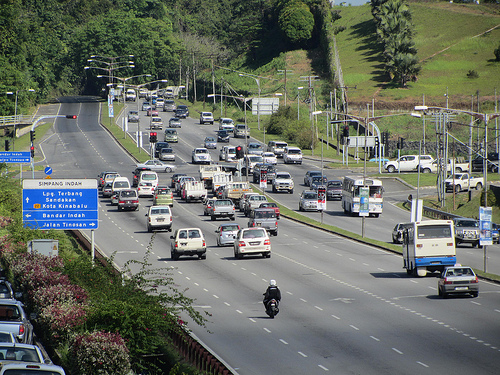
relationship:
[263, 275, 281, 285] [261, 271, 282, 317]
helmet on rider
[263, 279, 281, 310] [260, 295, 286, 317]
man riding motorcycle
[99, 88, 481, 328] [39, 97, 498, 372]
traffic on highway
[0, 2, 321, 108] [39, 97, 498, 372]
trees near highway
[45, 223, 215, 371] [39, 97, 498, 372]
bushes near highway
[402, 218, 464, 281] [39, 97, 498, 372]
vehicles entering highway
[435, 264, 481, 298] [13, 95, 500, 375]
cars on highway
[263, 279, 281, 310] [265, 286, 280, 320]
man on motorcyle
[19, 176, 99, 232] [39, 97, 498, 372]
blue sign on highway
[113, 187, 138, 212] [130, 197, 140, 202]
car with light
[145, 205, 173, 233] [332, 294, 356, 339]
car on road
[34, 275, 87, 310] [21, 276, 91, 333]
flowers on hedge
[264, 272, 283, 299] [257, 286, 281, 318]
man on motorcycle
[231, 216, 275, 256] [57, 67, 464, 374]
jeep on highway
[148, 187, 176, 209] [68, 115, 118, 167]
jeep on highway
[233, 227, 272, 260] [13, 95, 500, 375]
car on highway